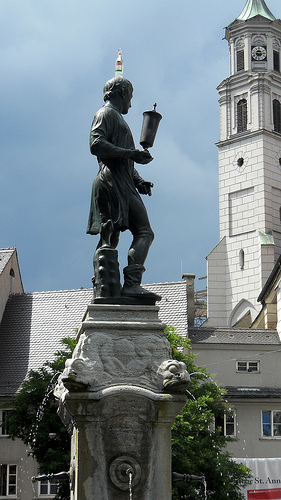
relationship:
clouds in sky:
[0, 0, 281, 211] [0, 0, 279, 291]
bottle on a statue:
[114, 47, 123, 76] [86, 74, 163, 305]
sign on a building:
[223, 456, 280, 498] [0, 248, 278, 498]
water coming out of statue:
[189, 367, 207, 377] [86, 74, 163, 305]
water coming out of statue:
[185, 387, 197, 400] [86, 74, 163, 305]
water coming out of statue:
[45, 372, 54, 397] [86, 74, 163, 305]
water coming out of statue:
[126, 469, 135, 494] [86, 74, 163, 305]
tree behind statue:
[0, 321, 255, 499] [86, 74, 163, 305]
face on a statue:
[119, 89, 132, 114] [86, 74, 163, 305]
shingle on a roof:
[89, 291, 92, 294] [0, 288, 94, 409]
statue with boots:
[86, 74, 163, 305] [88, 240, 171, 305]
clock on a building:
[238, 39, 272, 75] [190, 1, 271, 447]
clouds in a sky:
[0, 0, 242, 290] [0, 0, 281, 327]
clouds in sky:
[8, 9, 81, 72] [3, 3, 220, 268]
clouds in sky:
[1, 7, 102, 87] [3, 3, 220, 268]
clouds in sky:
[169, 5, 215, 143] [3, 3, 220, 268]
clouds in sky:
[10, 139, 84, 255] [3, 3, 220, 268]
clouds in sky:
[156, 142, 213, 243] [3, 3, 220, 268]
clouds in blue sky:
[157, 142, 210, 193] [0, 0, 279, 289]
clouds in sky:
[0, 4, 190, 78] [2, 3, 88, 247]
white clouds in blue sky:
[167, 144, 206, 183] [1, 0, 279, 328]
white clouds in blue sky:
[162, 137, 203, 190] [126, 25, 176, 76]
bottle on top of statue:
[112, 42, 125, 76] [86, 74, 163, 305]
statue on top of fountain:
[86, 74, 163, 305] [54, 304, 191, 498]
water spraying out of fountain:
[77, 236, 184, 340] [24, 298, 210, 498]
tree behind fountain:
[0, 321, 255, 499] [8, 44, 251, 499]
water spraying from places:
[15, 367, 61, 498] [14, 371, 257, 498]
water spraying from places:
[182, 387, 230, 496] [14, 371, 257, 498]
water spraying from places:
[124, 471, 135, 499] [14, 371, 257, 498]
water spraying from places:
[190, 370, 257, 493] [14, 371, 257, 498]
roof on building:
[6, 291, 72, 384] [2, 246, 193, 495]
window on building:
[214, 406, 236, 438] [184, 1, 280, 457]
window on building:
[260, 407, 280, 436] [184, 1, 280, 457]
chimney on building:
[181, 272, 194, 326] [188, 326, 278, 456]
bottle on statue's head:
[112, 46, 126, 79] [101, 75, 134, 111]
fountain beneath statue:
[77, 434, 166, 498] [79, 73, 164, 306]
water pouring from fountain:
[126, 471, 137, 497] [54, 304, 191, 498]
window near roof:
[235, 43, 245, 72] [223, 1, 279, 40]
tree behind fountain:
[12, 312, 259, 498] [54, 304, 191, 498]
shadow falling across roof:
[2, 290, 29, 392] [3, 269, 195, 402]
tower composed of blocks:
[201, 1, 277, 324] [223, 177, 260, 190]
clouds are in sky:
[0, 0, 280, 291] [0, 0, 279, 291]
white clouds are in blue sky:
[0, 26, 88, 103] [2, 0, 218, 281]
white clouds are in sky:
[2, 9, 85, 103] [11, 7, 71, 177]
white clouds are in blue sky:
[156, 144, 210, 186] [13, 1, 221, 78]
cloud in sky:
[132, 52, 235, 210] [1, 0, 237, 331]